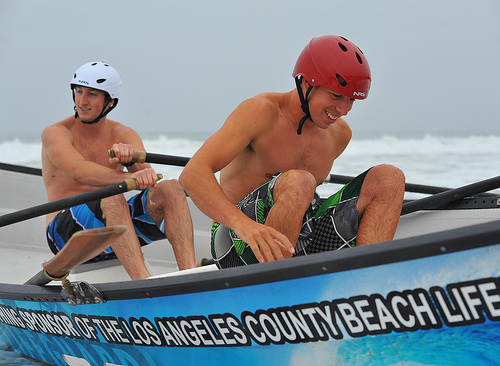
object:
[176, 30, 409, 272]
men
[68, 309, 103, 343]
words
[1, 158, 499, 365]
boat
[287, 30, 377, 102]
helmet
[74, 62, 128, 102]
helmet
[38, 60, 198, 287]
man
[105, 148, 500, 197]
oar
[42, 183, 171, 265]
swimming suit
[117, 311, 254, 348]
los angeles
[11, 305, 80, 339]
sponsor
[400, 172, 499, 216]
oar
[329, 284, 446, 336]
beach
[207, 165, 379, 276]
swimming suit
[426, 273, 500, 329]
life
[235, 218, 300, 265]
hand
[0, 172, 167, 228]
oar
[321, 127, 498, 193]
waves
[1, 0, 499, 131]
sky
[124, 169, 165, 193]
handle